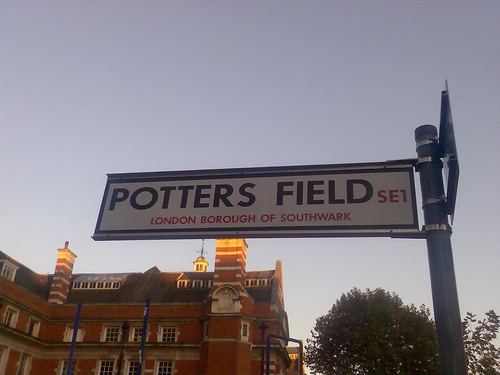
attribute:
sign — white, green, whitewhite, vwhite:
[91, 162, 416, 233]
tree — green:
[348, 297, 394, 339]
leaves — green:
[395, 318, 432, 349]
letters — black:
[125, 175, 368, 208]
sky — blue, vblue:
[66, 35, 91, 58]